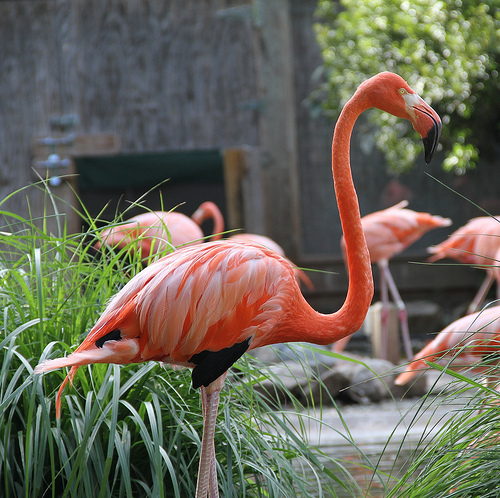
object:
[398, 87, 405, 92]
eye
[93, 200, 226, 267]
flamingo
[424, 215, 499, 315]
flamingo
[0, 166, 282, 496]
water grass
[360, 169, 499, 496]
water grass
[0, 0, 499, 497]
zoo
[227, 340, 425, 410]
boulder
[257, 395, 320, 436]
water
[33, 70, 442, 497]
bird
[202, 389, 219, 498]
legs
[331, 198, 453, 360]
flamingo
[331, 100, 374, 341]
neck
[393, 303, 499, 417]
bird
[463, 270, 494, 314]
legs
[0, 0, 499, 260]
wall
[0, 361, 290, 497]
grass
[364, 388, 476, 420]
water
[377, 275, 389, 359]
leg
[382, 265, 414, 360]
leg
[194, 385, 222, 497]
legs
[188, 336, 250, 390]
black feathers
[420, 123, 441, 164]
beak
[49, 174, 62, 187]
light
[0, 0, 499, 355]
building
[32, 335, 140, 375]
tail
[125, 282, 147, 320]
feather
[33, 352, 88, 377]
feather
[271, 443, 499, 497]
water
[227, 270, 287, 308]
feathers